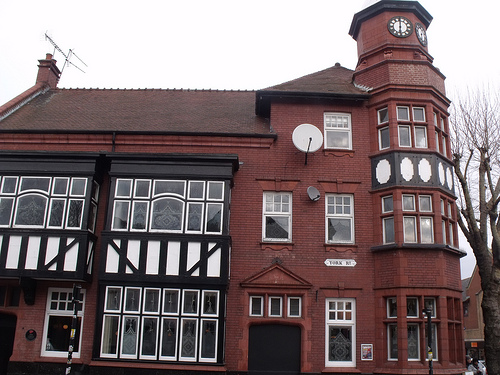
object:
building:
[0, 0, 470, 375]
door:
[247, 320, 303, 375]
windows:
[102, 283, 125, 314]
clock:
[385, 13, 414, 39]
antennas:
[43, 31, 70, 63]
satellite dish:
[290, 122, 326, 167]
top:
[0, 0, 455, 163]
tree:
[450, 82, 499, 375]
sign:
[323, 258, 358, 268]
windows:
[260, 188, 295, 247]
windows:
[113, 178, 136, 201]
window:
[96, 150, 242, 288]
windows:
[248, 295, 265, 318]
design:
[370, 149, 457, 196]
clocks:
[414, 22, 429, 48]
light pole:
[65, 281, 82, 375]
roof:
[0, 49, 370, 140]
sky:
[0, 0, 500, 140]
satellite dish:
[306, 185, 322, 202]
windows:
[374, 103, 391, 126]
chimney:
[35, 52, 63, 90]